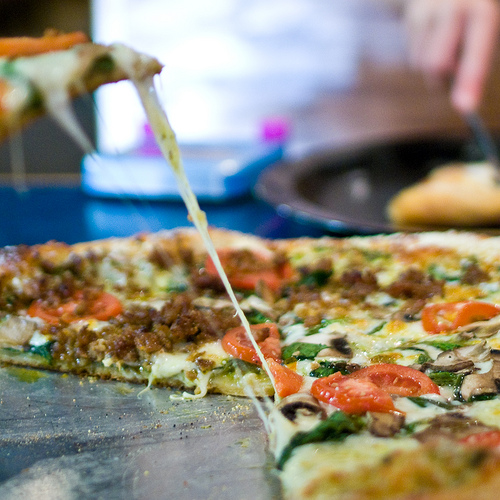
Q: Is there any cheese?
A: Yes, there is cheese.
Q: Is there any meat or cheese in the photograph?
A: Yes, there is cheese.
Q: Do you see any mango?
A: No, there are no mangoes.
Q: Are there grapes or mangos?
A: No, there are no mangos or grapes.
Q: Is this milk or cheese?
A: This is cheese.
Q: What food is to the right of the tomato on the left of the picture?
A: The food is cheese.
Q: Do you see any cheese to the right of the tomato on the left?
A: Yes, there is cheese to the right of the tomato.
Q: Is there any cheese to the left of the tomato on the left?
A: No, the cheese is to the right of the tomato.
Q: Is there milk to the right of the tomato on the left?
A: No, there is cheese to the right of the tomato.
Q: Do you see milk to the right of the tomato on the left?
A: No, there is cheese to the right of the tomato.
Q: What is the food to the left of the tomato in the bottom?
A: The food is cheese.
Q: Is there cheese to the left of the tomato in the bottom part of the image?
A: Yes, there is cheese to the left of the tomato.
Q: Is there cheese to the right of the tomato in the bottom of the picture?
A: No, the cheese is to the left of the tomato.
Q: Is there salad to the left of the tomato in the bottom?
A: No, there is cheese to the left of the tomato.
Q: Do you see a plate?
A: Yes, there is a plate.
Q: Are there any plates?
A: Yes, there is a plate.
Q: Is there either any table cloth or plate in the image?
A: Yes, there is a plate.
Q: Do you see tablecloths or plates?
A: Yes, there is a plate.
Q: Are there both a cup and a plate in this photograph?
A: No, there is a plate but no cups.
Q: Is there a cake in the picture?
A: No, there are no cakes.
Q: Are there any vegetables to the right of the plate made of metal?
A: Yes, there is a vegetable to the right of the plate.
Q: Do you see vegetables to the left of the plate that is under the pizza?
A: No, the vegetable is to the right of the plate.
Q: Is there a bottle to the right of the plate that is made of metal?
A: No, there is a vegetable to the right of the plate.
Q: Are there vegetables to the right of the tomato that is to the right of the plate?
A: Yes, there is a vegetable to the right of the tomato.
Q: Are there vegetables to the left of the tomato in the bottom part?
A: No, the vegetable is to the right of the tomato.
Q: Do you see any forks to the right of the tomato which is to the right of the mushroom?
A: No, there is a vegetable to the right of the tomato.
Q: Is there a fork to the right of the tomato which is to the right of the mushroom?
A: No, there is a vegetable to the right of the tomato.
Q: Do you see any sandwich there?
A: No, there are no sandwiches.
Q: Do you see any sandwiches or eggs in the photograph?
A: No, there are no sandwiches or eggs.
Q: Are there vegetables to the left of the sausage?
A: Yes, there is a vegetable to the left of the sausage.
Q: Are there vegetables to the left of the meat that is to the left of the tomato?
A: Yes, there is a vegetable to the left of the sausage.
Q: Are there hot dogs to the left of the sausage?
A: No, there is a vegetable to the left of the sausage.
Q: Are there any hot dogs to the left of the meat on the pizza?
A: No, there is a vegetable to the left of the sausage.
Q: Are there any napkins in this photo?
A: No, there are no napkins.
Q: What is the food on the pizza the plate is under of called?
A: The food is a sausage.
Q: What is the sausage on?
A: The sausage is on the pizza.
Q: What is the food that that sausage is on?
A: The food is a pizza.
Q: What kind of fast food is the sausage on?
A: The sausage is on the pizza.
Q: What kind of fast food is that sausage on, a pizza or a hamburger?
A: The sausage is on a pizza.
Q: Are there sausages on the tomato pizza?
A: Yes, there is a sausage on the pizza.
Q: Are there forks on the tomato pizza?
A: No, there is a sausage on the pizza.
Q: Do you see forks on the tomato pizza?
A: No, there is a sausage on the pizza.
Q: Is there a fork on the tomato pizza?
A: No, there is a sausage on the pizza.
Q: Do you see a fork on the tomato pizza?
A: No, there is a sausage on the pizza.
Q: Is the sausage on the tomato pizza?
A: Yes, the sausage is on the pizza.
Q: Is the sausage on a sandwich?
A: No, the sausage is on the pizza.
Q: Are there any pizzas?
A: Yes, there is a pizza.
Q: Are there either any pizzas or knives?
A: Yes, there is a pizza.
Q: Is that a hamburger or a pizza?
A: That is a pizza.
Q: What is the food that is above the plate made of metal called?
A: The food is a pizza.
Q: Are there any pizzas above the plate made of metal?
A: Yes, there is a pizza above the plate.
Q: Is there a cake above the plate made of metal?
A: No, there is a pizza above the plate.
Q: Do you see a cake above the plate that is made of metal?
A: No, there is a pizza above the plate.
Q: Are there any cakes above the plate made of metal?
A: No, there is a pizza above the plate.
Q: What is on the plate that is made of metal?
A: The pizza is on the plate.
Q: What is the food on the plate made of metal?
A: The food is a pizza.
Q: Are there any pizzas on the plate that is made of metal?
A: Yes, there is a pizza on the plate.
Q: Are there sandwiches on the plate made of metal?
A: No, there is a pizza on the plate.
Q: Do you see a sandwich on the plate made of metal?
A: No, there is a pizza on the plate.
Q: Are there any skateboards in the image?
A: No, there are no skateboards.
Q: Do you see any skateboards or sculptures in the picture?
A: No, there are no skateboards or sculptures.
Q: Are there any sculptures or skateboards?
A: No, there are no skateboards or sculptures.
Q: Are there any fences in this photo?
A: No, there are no fences.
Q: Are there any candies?
A: No, there are no candies.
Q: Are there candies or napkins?
A: No, there are no candies or napkins.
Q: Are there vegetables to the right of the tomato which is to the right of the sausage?
A: Yes, there is a vegetable to the right of the tomato.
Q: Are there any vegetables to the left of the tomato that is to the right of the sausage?
A: No, the vegetable is to the right of the tomato.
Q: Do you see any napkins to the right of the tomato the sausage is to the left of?
A: No, there is a vegetable to the right of the tomato.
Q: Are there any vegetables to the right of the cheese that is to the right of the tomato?
A: Yes, there is a vegetable to the right of the cheese.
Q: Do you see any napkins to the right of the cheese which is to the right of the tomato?
A: No, there is a vegetable to the right of the cheese.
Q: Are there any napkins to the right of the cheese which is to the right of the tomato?
A: No, there is a vegetable to the right of the cheese.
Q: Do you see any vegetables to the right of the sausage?
A: Yes, there is a vegetable to the right of the sausage.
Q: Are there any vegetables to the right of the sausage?
A: Yes, there is a vegetable to the right of the sausage.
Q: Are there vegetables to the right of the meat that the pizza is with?
A: Yes, there is a vegetable to the right of the sausage.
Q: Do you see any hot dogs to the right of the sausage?
A: No, there is a vegetable to the right of the sausage.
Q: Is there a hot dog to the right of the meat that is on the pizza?
A: No, there is a vegetable to the right of the sausage.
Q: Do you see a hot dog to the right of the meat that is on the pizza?
A: No, there is a vegetable to the right of the sausage.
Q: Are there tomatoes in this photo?
A: Yes, there is a tomato.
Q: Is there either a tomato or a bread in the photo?
A: Yes, there is a tomato.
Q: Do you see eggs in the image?
A: No, there are no eggs.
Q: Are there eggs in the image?
A: No, there are no eggs.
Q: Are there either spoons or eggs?
A: No, there are no eggs or spoons.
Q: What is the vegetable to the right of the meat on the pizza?
A: The vegetable is a tomato.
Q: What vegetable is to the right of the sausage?
A: The vegetable is a tomato.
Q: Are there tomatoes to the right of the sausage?
A: Yes, there is a tomato to the right of the sausage.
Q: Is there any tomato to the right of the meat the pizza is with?
A: Yes, there is a tomato to the right of the sausage.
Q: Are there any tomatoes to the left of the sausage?
A: No, the tomato is to the right of the sausage.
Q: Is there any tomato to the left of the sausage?
A: No, the tomato is to the right of the sausage.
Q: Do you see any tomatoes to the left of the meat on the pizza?
A: No, the tomato is to the right of the sausage.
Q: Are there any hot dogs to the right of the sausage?
A: No, there is a tomato to the right of the sausage.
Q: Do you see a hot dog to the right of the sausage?
A: No, there is a tomato to the right of the sausage.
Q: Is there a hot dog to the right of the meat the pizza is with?
A: No, there is a tomato to the right of the sausage.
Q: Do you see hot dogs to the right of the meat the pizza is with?
A: No, there is a tomato to the right of the sausage.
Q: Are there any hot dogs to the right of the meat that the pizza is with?
A: No, there is a tomato to the right of the sausage.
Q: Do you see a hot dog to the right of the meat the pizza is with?
A: No, there is a tomato to the right of the sausage.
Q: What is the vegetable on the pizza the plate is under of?
A: The vegetable is a tomato.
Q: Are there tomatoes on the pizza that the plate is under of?
A: Yes, there is a tomato on the pizza.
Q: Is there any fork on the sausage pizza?
A: No, there is a tomato on the pizza.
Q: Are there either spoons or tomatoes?
A: Yes, there is a tomato.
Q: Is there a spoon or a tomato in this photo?
A: Yes, there is a tomato.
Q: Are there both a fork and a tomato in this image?
A: No, there is a tomato but no forks.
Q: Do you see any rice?
A: No, there is no rice.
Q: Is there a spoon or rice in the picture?
A: No, there are no rice or spoons.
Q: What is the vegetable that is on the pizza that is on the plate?
A: The vegetable is a tomato.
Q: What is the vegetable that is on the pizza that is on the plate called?
A: The vegetable is a tomato.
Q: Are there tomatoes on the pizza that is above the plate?
A: Yes, there is a tomato on the pizza.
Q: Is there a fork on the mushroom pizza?
A: No, there is a tomato on the pizza.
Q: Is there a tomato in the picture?
A: Yes, there is a tomato.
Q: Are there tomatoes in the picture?
A: Yes, there is a tomato.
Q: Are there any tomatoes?
A: Yes, there is a tomato.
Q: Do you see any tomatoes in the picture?
A: Yes, there is a tomato.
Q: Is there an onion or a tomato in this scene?
A: Yes, there is a tomato.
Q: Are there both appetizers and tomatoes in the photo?
A: No, there is a tomato but no appetizers.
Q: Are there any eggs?
A: No, there are no eggs.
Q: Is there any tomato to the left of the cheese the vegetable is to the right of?
A: Yes, there is a tomato to the left of the cheese.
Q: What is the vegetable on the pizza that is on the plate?
A: The vegetable is a tomato.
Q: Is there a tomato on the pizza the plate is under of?
A: Yes, there is a tomato on the pizza.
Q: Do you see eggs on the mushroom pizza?
A: No, there is a tomato on the pizza.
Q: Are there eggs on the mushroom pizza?
A: No, there is a tomato on the pizza.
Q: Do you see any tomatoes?
A: Yes, there is a tomato.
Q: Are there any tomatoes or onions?
A: Yes, there is a tomato.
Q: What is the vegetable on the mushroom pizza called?
A: The vegetable is a tomato.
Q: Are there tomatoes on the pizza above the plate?
A: Yes, there is a tomato on the pizza.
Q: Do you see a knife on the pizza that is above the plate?
A: No, there is a tomato on the pizza.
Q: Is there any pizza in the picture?
A: Yes, there is a pizza.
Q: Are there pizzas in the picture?
A: Yes, there is a pizza.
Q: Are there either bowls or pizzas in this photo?
A: Yes, there is a pizza.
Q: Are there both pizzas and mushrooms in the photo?
A: Yes, there are both a pizza and a mushroom.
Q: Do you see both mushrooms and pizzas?
A: Yes, there are both a pizza and a mushroom.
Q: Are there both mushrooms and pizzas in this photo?
A: Yes, there are both a pizza and a mushroom.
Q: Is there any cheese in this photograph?
A: Yes, there is cheese.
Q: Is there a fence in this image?
A: No, there are no fences.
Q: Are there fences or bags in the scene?
A: No, there are no fences or bags.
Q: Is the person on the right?
A: Yes, the person is on the right of the image.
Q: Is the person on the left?
A: No, the person is on the right of the image.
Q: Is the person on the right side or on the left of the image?
A: The person is on the right of the image.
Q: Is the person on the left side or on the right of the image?
A: The person is on the right of the image.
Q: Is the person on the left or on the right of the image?
A: The person is on the right of the image.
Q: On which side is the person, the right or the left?
A: The person is on the right of the image.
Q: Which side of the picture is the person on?
A: The person is on the right of the image.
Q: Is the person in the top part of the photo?
A: Yes, the person is in the top of the image.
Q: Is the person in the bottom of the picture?
A: No, the person is in the top of the image.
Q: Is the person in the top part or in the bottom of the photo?
A: The person is in the top of the image.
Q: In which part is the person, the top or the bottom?
A: The person is in the top of the image.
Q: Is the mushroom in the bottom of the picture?
A: Yes, the mushroom is in the bottom of the image.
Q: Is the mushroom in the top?
A: No, the mushroom is in the bottom of the image.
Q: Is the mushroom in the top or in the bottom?
A: The mushroom is in the bottom of the image.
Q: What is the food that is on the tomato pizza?
A: The food is a mushroom.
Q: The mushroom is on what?
A: The mushroom is on the pizza.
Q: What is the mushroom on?
A: The mushroom is on the pizza.